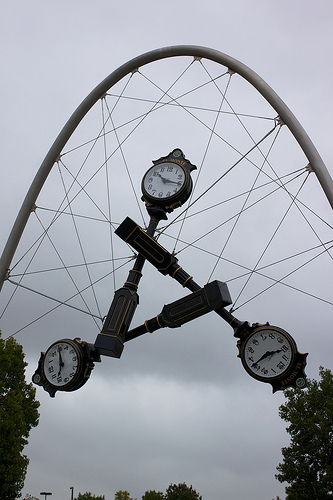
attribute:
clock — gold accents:
[43, 342, 77, 385]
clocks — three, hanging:
[42, 160, 313, 400]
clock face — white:
[139, 147, 199, 214]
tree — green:
[271, 365, 331, 498]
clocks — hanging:
[23, 97, 314, 406]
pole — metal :
[100, 211, 173, 323]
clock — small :
[134, 146, 211, 208]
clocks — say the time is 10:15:
[27, 333, 100, 402]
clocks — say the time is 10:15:
[227, 311, 314, 395]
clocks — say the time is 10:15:
[134, 144, 200, 223]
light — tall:
[41, 491, 52, 498]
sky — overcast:
[14, 12, 324, 103]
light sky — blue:
[24, 360, 228, 401]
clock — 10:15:
[121, 143, 230, 260]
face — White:
[153, 169, 179, 196]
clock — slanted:
[140, 160, 188, 199]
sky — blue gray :
[0, 186, 332, 376]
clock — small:
[142, 160, 186, 208]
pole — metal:
[100, 208, 168, 345]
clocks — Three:
[36, 149, 304, 403]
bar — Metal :
[232, 70, 310, 203]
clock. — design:
[237, 326, 307, 379]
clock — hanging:
[129, 148, 203, 213]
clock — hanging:
[227, 324, 315, 388]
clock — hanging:
[233, 317, 308, 388]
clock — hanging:
[18, 332, 110, 405]